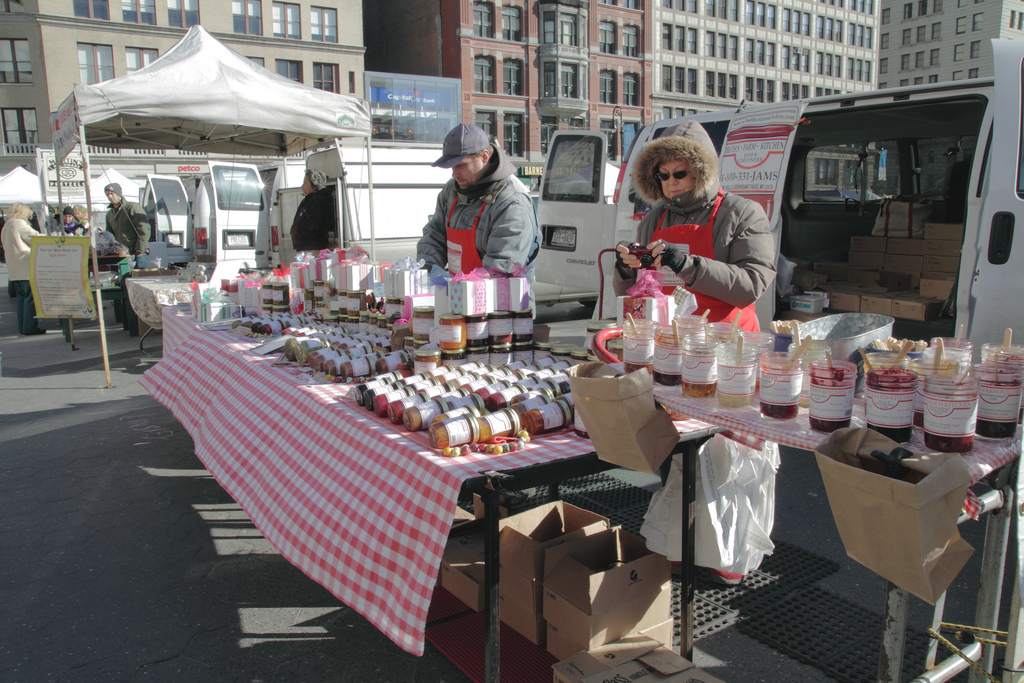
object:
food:
[190, 246, 575, 456]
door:
[205, 161, 270, 292]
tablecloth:
[136, 306, 767, 683]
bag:
[639, 433, 782, 575]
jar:
[428, 413, 479, 448]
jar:
[477, 407, 521, 443]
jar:
[524, 400, 571, 435]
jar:
[403, 398, 450, 432]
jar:
[485, 384, 528, 413]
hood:
[631, 120, 719, 202]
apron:
[650, 188, 760, 333]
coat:
[613, 120, 778, 333]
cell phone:
[628, 250, 658, 266]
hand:
[616, 240, 643, 268]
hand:
[660, 239, 688, 274]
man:
[417, 123, 544, 321]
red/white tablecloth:
[137, 307, 766, 657]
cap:
[432, 123, 490, 169]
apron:
[447, 195, 487, 277]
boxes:
[850, 236, 887, 252]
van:
[535, 39, 1024, 367]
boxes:
[497, 500, 674, 661]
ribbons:
[449, 262, 523, 286]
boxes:
[448, 267, 495, 316]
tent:
[50, 24, 375, 388]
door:
[719, 101, 809, 330]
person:
[613, 119, 777, 585]